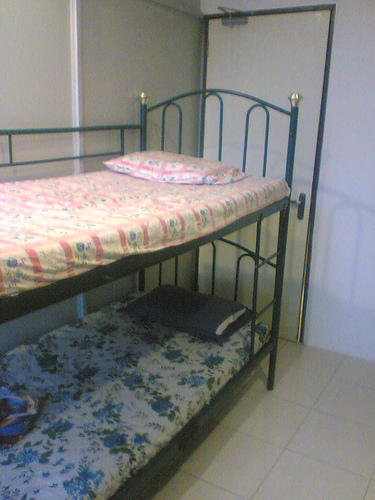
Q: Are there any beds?
A: Yes, there is a bed.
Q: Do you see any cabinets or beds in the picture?
A: Yes, there is a bed.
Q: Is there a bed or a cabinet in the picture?
A: Yes, there is a bed.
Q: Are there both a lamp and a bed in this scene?
A: No, there is a bed but no lamps.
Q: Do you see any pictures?
A: No, there are no pictures.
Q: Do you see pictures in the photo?
A: No, there are no pictures.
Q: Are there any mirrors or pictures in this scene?
A: No, there are no pictures or mirrors.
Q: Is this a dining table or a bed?
A: This is a bed.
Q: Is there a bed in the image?
A: Yes, there is a bed.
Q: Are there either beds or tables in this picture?
A: Yes, there is a bed.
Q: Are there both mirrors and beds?
A: No, there is a bed but no mirrors.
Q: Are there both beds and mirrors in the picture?
A: No, there is a bed but no mirrors.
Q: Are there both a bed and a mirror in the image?
A: No, there is a bed but no mirrors.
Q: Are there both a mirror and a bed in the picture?
A: No, there is a bed but no mirrors.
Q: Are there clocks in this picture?
A: No, there are no clocks.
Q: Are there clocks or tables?
A: No, there are no clocks or tables.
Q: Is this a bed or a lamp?
A: This is a bed.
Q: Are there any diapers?
A: No, there are no diapers.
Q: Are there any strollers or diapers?
A: No, there are no diapers or strollers.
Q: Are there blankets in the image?
A: Yes, there is a blanket.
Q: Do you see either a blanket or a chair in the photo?
A: Yes, there is a blanket.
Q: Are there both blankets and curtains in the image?
A: No, there is a blanket but no curtains.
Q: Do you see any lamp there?
A: No, there are no lamps.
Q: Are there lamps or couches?
A: No, there are no lamps or couches.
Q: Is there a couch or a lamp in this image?
A: No, there are no lamps or couches.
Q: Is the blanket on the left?
A: Yes, the blanket is on the left of the image.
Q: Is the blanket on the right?
A: No, the blanket is on the left of the image.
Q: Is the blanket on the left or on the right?
A: The blanket is on the left of the image.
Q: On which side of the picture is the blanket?
A: The blanket is on the left of the image.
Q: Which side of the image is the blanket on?
A: The blanket is on the left of the image.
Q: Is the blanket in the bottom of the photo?
A: Yes, the blanket is in the bottom of the image.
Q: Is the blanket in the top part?
A: No, the blanket is in the bottom of the image.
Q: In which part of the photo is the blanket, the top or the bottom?
A: The blanket is in the bottom of the image.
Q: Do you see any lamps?
A: No, there are no lamps.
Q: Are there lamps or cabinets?
A: No, there are no lamps or cabinets.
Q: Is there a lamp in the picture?
A: No, there are no lamps.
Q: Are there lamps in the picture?
A: No, there are no lamps.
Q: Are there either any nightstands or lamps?
A: No, there are no lamps or nightstands.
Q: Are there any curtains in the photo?
A: No, there are no curtains.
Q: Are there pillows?
A: Yes, there is a pillow.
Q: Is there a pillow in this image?
A: Yes, there is a pillow.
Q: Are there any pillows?
A: Yes, there is a pillow.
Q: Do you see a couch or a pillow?
A: Yes, there is a pillow.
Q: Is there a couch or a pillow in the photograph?
A: Yes, there is a pillow.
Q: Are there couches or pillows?
A: Yes, there is a pillow.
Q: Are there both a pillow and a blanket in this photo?
A: Yes, there are both a pillow and a blanket.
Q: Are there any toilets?
A: No, there are no toilets.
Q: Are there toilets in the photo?
A: No, there are no toilets.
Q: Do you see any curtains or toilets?
A: No, there are no toilets or curtains.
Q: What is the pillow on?
A: The pillow is on the bed.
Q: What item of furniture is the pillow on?
A: The pillow is on the bed.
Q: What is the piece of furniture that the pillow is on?
A: The piece of furniture is a bed.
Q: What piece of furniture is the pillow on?
A: The pillow is on the bed.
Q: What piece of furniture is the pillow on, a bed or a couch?
A: The pillow is on a bed.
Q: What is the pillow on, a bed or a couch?
A: The pillow is on a bed.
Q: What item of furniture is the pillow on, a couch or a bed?
A: The pillow is on a bed.